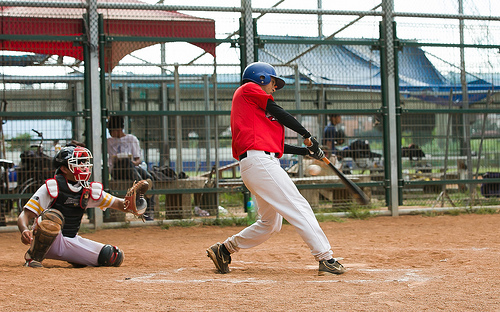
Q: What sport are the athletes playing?
A: Baseball.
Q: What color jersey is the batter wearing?
A: Red.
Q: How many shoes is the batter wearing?
A: Two.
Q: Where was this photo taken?
A: A baseball field.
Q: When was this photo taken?
A: Daytime.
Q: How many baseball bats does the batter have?
A: One.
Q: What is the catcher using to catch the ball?
A: A glove.